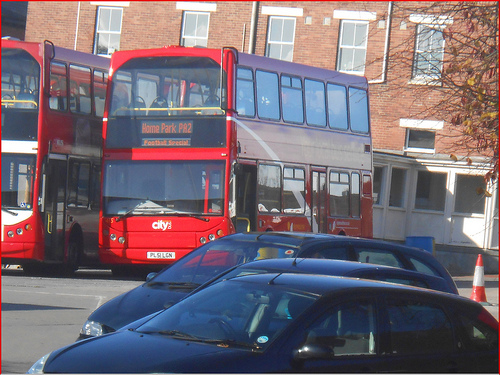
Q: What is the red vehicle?
A: Bus.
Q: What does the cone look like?
A: Orange and white.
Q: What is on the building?
A: Window.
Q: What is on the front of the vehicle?
A: Bus window.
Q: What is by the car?
A: Red bus.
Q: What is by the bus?
A: 3 black cars.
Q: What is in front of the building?
A: Bus on street.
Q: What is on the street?
A: Bus.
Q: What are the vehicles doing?
A: Taking people home.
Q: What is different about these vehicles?
A: Two levels.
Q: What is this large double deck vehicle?
A: Bus.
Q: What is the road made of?
A: Asphalt.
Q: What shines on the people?
A: Sun.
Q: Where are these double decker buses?
A: Road.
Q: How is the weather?
A: Sunny.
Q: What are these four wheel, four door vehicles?
A: Cars.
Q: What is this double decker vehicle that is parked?
A: Bus.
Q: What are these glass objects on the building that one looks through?
A: Windows.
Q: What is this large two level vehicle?
A: Bus.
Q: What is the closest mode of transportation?
A: Car.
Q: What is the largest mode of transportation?
A: Buses.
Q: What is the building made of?
A: Brick.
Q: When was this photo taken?
A: During the daytime.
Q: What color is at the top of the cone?
A: Orange.